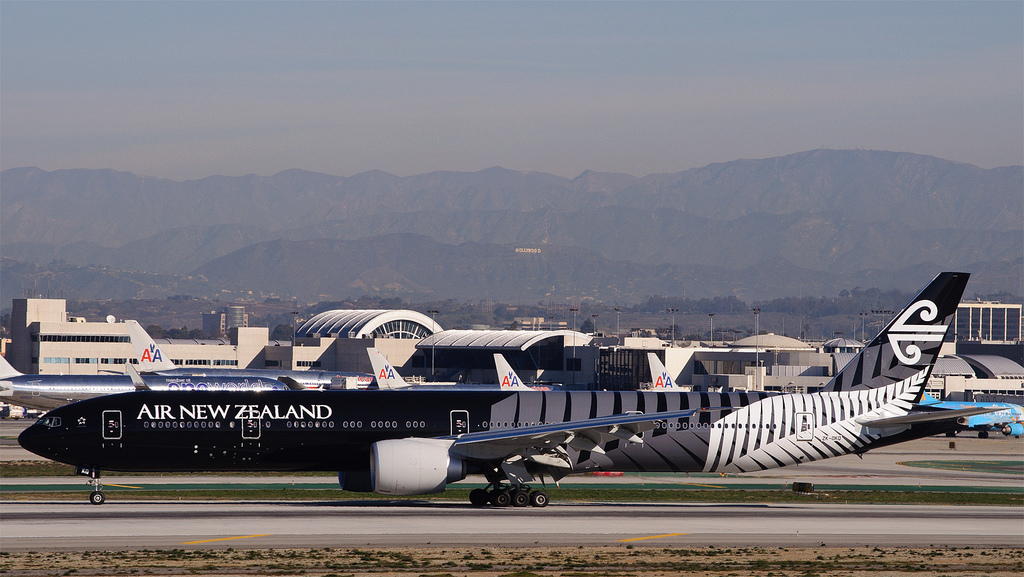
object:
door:
[102, 409, 122, 439]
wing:
[452, 409, 698, 449]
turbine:
[336, 431, 379, 496]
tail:
[818, 271, 972, 394]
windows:
[143, 420, 427, 428]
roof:
[291, 309, 444, 339]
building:
[293, 309, 446, 376]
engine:
[370, 436, 468, 497]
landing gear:
[468, 455, 550, 508]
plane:
[13, 271, 1012, 507]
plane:
[98, 319, 380, 391]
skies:
[0, 0, 1024, 182]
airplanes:
[0, 272, 1022, 508]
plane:
[640, 347, 687, 394]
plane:
[0, 349, 291, 414]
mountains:
[0, 147, 1024, 338]